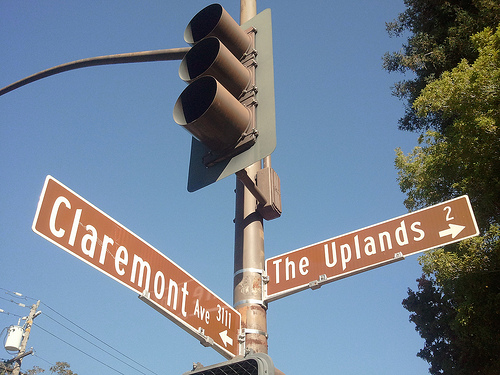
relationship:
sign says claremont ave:
[30, 175, 240, 358] [48, 193, 212, 328]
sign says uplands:
[261, 195, 481, 308] [271, 215, 427, 290]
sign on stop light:
[30, 175, 240, 358] [168, 2, 283, 194]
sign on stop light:
[261, 195, 481, 308] [168, 2, 283, 194]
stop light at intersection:
[168, 2, 283, 194] [10, 161, 489, 370]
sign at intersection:
[30, 175, 240, 358] [10, 161, 489, 370]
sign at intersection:
[261, 195, 481, 308] [10, 161, 489, 370]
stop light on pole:
[168, 2, 283, 194] [235, 3, 269, 362]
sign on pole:
[30, 175, 240, 358] [235, 3, 269, 362]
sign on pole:
[261, 195, 481, 308] [235, 3, 269, 362]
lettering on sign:
[270, 203, 455, 287] [261, 195, 481, 308]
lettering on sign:
[47, 193, 235, 337] [30, 175, 240, 358]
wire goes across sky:
[42, 302, 156, 374] [0, 1, 488, 372]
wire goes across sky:
[41, 310, 146, 374] [0, 1, 488, 372]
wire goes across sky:
[3, 296, 24, 308] [0, 1, 488, 372]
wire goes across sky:
[34, 322, 123, 374] [0, 1, 488, 372]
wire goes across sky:
[32, 353, 68, 374] [0, 1, 488, 372]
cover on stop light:
[170, 73, 250, 154] [168, 2, 283, 194]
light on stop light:
[178, 35, 252, 100] [168, 2, 283, 194]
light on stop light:
[183, 3, 253, 61] [168, 2, 283, 194]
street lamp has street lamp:
[0, 45, 194, 98] [0, 45, 194, 98]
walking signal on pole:
[180, 351, 274, 374] [235, 3, 269, 362]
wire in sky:
[42, 302, 156, 374] [0, 1, 488, 372]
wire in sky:
[41, 310, 146, 374] [0, 1, 488, 372]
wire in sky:
[34, 322, 123, 374] [0, 1, 488, 372]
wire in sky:
[32, 353, 68, 374] [0, 1, 488, 372]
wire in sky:
[3, 296, 24, 308] [0, 1, 488, 372]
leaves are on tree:
[379, 47, 414, 74] [383, 1, 499, 137]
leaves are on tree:
[408, 58, 474, 116] [391, 62, 499, 346]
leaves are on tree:
[403, 285, 427, 319] [401, 272, 483, 374]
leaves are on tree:
[466, 24, 498, 62] [383, 1, 499, 137]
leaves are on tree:
[381, 13, 408, 40] [383, 1, 499, 137]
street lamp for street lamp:
[0, 45, 194, 98] [0, 45, 194, 98]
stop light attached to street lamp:
[168, 2, 283, 194] [0, 45, 194, 98]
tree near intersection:
[391, 62, 499, 346] [10, 161, 489, 370]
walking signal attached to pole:
[180, 351, 274, 374] [235, 3, 269, 362]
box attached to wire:
[3, 323, 25, 356] [32, 353, 68, 374]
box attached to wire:
[3, 323, 25, 356] [34, 322, 123, 374]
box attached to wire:
[3, 323, 25, 356] [41, 310, 146, 374]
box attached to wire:
[3, 323, 25, 356] [42, 302, 156, 374]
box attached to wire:
[3, 323, 25, 356] [3, 296, 24, 308]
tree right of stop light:
[391, 62, 499, 346] [168, 2, 283, 194]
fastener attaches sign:
[234, 267, 268, 284] [261, 195, 481, 308]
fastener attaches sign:
[234, 297, 271, 312] [261, 195, 481, 308]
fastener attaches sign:
[238, 324, 269, 342] [30, 175, 240, 358]